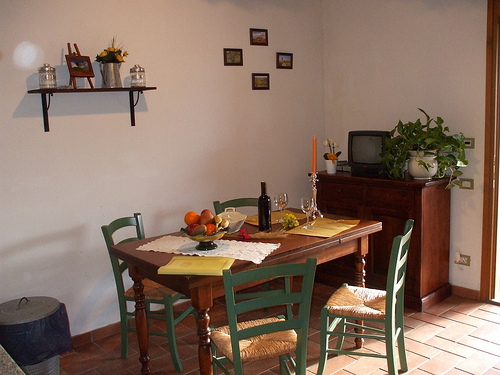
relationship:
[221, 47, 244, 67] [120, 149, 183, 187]
picture on wall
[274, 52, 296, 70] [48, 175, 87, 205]
picture on wall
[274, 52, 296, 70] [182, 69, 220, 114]
picture on wall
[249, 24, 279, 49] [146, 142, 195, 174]
picture on wall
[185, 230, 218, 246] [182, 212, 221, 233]
fruit in basket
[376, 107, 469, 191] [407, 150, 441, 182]
plant in pot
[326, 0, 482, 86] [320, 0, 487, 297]
part of wall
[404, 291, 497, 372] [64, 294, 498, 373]
part of floor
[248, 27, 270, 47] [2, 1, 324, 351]
picture on wall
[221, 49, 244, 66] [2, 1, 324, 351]
picture on wall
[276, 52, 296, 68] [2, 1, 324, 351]
picture on wall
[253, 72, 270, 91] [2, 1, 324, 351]
picture on wall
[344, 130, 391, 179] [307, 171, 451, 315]
tv on cabinet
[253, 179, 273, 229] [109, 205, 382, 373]
bottle on table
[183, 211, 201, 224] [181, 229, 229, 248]
fruit in bowl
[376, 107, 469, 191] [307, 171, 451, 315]
plant on cabinet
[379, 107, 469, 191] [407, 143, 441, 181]
plant in pot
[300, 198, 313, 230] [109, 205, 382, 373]
glass on table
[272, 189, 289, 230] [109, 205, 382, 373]
glass on table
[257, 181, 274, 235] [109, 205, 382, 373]
bottle on table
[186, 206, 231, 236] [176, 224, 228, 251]
fruit in basket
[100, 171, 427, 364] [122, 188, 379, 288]
chairs are next to table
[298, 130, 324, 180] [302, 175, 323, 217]
candle inside of holder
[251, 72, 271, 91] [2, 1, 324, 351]
picture are hanging on wall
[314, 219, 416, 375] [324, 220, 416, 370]
chair attached to chair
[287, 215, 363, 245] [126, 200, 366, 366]
placemat on top of table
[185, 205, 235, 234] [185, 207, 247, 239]
fruit inside of bowl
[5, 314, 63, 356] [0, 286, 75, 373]
bag inside of can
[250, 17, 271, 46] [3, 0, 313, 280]
frame hanging on wall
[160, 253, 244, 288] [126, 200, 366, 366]
placemat on top of table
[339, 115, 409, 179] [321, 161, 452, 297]
tv on top of table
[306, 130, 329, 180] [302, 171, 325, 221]
candlestick inside of candlestick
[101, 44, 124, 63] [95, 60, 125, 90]
flowers inside of can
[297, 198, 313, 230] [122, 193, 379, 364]
glass on top of table